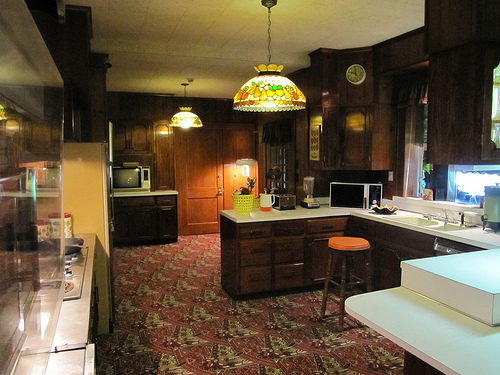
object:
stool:
[315, 234, 376, 333]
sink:
[377, 208, 467, 238]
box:
[398, 245, 499, 329]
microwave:
[325, 181, 386, 213]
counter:
[219, 204, 499, 374]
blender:
[298, 174, 321, 209]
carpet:
[95, 231, 412, 375]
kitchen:
[1, 2, 499, 375]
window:
[401, 85, 431, 195]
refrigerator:
[60, 138, 114, 336]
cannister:
[58, 211, 72, 240]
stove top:
[54, 244, 93, 303]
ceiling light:
[230, 63, 305, 112]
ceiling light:
[168, 103, 205, 128]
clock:
[344, 63, 366, 86]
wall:
[251, 3, 499, 212]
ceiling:
[56, 0, 426, 101]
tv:
[109, 162, 153, 195]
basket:
[230, 191, 255, 215]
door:
[171, 118, 224, 232]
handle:
[216, 186, 226, 198]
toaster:
[271, 193, 297, 213]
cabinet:
[303, 233, 348, 287]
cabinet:
[111, 207, 156, 243]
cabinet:
[330, 105, 376, 171]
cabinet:
[366, 239, 403, 289]